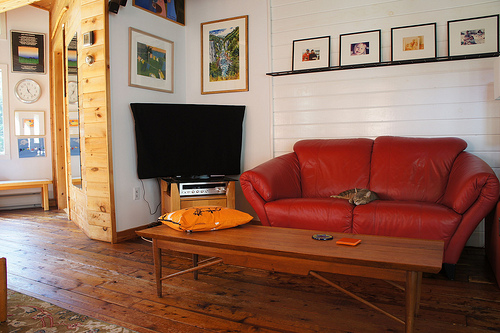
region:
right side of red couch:
[383, 141, 449, 191]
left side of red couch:
[306, 145, 359, 185]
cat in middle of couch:
[328, 185, 377, 207]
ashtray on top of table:
[308, 228, 337, 243]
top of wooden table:
[256, 237, 298, 248]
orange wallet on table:
[337, 232, 361, 249]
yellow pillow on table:
[158, 203, 248, 229]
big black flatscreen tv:
[128, 96, 247, 181]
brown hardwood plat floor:
[78, 275, 123, 310]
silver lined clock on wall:
[11, 78, 46, 103]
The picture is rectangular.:
[443, 8, 498, 61]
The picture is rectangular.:
[384, 16, 441, 67]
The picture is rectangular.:
[284, 28, 333, 82]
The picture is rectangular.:
[194, 8, 255, 102]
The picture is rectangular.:
[123, 16, 181, 96]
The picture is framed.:
[121, 19, 183, 94]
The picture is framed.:
[283, 25, 333, 73]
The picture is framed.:
[333, 20, 385, 75]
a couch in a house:
[196, 115, 497, 247]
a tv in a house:
[132, 93, 287, 190]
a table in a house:
[136, 182, 414, 310]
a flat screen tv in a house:
[138, 58, 248, 216]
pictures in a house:
[275, 30, 335, 69]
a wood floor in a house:
[22, 223, 138, 284]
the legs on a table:
[138, 255, 468, 301]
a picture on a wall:
[117, 15, 191, 99]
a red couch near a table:
[209, 126, 431, 280]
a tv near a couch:
[129, 81, 441, 205]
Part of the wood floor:
[60, 255, 95, 287]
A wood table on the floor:
[131, 208, 447, 330]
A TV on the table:
[124, 96, 260, 183]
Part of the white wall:
[328, 85, 402, 110]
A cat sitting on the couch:
[329, 183, 380, 208]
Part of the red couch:
[326, 149, 361, 166]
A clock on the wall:
[11, 75, 45, 103]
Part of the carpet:
[22, 312, 49, 321]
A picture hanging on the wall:
[198, 13, 254, 95]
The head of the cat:
[351, 184, 373, 206]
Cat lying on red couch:
[240, 131, 495, 228]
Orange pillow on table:
[142, 202, 256, 279]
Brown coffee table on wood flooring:
[115, 230, 474, 326]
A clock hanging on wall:
[4, 78, 49, 103]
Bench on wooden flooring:
[0, 174, 57, 216]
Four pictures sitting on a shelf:
[270, 12, 498, 71]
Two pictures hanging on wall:
[121, 12, 249, 95]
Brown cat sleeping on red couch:
[245, 141, 468, 226]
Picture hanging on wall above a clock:
[5, 25, 50, 102]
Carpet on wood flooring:
[22, 254, 142, 329]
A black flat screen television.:
[132, 105, 246, 174]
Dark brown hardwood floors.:
[0, 205, 492, 331]